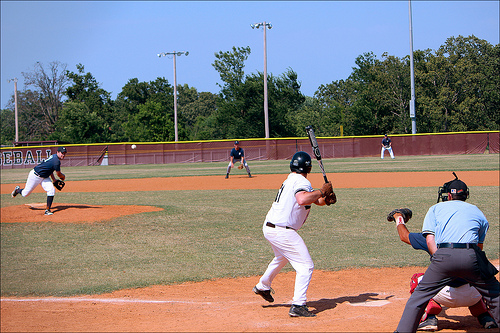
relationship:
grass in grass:
[0, 151, 499, 295] [0, 151, 499, 295]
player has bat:
[9, 138, 499, 326] [306, 123, 341, 202]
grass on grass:
[0, 151, 499, 295] [0, 151, 499, 295]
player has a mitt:
[9, 138, 499, 326] [374, 193, 431, 236]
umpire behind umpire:
[395, 170, 499, 333] [393, 179, 499, 333]